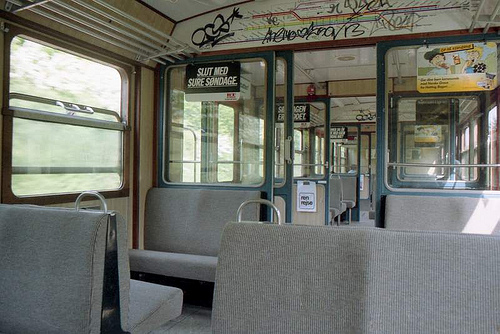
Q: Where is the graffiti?
A: Above the doors.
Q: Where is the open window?
A: On the left side.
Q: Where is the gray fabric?
A: On the seats.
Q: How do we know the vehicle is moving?
A: Scenery outside window is blurry.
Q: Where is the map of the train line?
A: Beneath graffiti.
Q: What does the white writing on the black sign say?
A: Slut med sure sondage.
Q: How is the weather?
A: Sunny.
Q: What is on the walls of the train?
A: Graffiti.